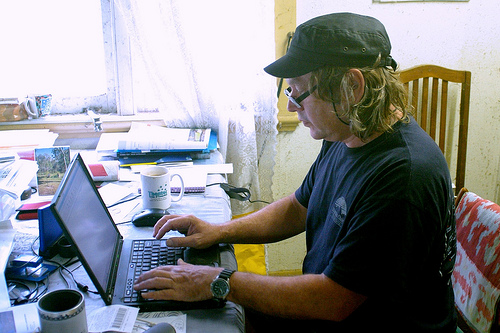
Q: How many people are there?
A: 1.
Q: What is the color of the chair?
A: Brown.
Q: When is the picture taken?
A: Daytime.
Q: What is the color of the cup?
A: White.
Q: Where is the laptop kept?
A: In the table.